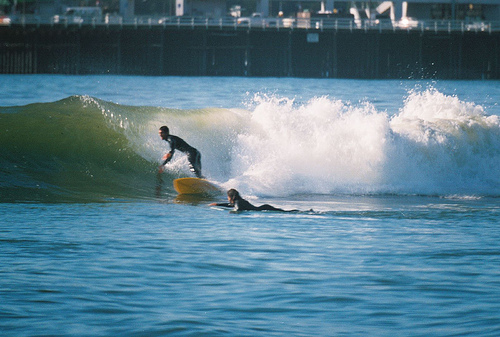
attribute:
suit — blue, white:
[172, 131, 203, 186]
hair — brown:
[224, 183, 241, 206]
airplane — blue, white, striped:
[24, 10, 91, 42]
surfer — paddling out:
[206, 182, 315, 219]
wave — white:
[231, 82, 495, 207]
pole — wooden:
[161, 158, 274, 223]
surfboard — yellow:
[173, 176, 223, 194]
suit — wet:
[170, 132, 215, 179]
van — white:
[211, 2, 268, 27]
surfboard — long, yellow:
[169, 171, 236, 205]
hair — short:
[157, 120, 176, 145]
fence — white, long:
[269, 15, 387, 31]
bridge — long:
[153, 10, 449, 43]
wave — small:
[12, 88, 499, 224]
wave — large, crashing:
[24, 77, 462, 213]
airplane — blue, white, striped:
[350, 7, 429, 32]